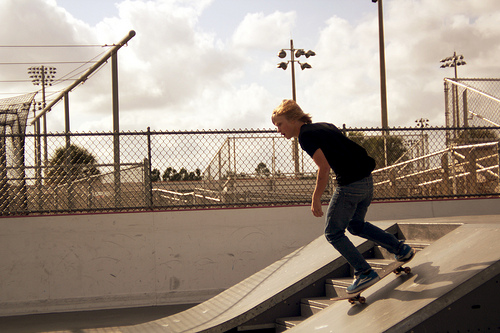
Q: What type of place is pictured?
A: It is a park.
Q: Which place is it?
A: It is a park.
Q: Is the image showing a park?
A: Yes, it is showing a park.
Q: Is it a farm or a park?
A: It is a park.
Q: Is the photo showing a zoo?
A: No, the picture is showing a park.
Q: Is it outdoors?
A: Yes, it is outdoors.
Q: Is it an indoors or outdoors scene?
A: It is outdoors.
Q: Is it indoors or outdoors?
A: It is outdoors.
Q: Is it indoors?
A: No, it is outdoors.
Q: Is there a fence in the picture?
A: Yes, there is a fence.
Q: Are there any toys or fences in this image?
A: Yes, there is a fence.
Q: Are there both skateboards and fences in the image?
A: Yes, there are both a fence and a skateboard.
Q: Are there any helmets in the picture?
A: No, there are no helmets.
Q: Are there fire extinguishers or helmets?
A: No, there are no helmets or fire extinguishers.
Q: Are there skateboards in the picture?
A: Yes, there is a skateboard.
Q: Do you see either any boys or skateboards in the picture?
A: Yes, there is a skateboard.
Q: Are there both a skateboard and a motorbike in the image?
A: No, there is a skateboard but no motorcycles.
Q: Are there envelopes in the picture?
A: No, there are no envelopes.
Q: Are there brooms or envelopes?
A: No, there are no envelopes or brooms.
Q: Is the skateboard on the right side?
A: Yes, the skateboard is on the right of the image.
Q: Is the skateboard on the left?
A: No, the skateboard is on the right of the image.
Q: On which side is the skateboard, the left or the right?
A: The skateboard is on the right of the image.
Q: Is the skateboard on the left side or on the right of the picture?
A: The skateboard is on the right of the image.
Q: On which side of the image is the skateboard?
A: The skateboard is on the right of the image.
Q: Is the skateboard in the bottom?
A: Yes, the skateboard is in the bottom of the image.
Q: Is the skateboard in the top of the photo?
A: No, the skateboard is in the bottom of the image.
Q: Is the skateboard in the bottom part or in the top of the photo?
A: The skateboard is in the bottom of the image.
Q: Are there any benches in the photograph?
A: No, there are no benches.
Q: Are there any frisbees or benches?
A: No, there are no benches or frisbees.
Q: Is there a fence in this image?
A: Yes, there is a fence.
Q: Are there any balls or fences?
A: Yes, there is a fence.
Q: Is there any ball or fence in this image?
A: Yes, there is a fence.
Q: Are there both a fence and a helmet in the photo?
A: No, there is a fence but no helmets.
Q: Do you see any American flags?
A: No, there are no American flags.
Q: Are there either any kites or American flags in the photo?
A: No, there are no American flags or kites.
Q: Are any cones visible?
A: No, there are no cones.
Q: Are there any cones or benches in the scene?
A: No, there are no cones or benches.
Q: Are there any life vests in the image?
A: No, there are no life vests.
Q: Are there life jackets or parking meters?
A: No, there are no life jackets or parking meters.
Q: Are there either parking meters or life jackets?
A: No, there are no life jackets or parking meters.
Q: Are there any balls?
A: No, there are no balls.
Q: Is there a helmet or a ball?
A: No, there are no balls or helmets.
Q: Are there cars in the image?
A: No, there are no cars.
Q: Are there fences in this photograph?
A: Yes, there is a fence.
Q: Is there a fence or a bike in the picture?
A: Yes, there is a fence.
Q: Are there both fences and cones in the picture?
A: No, there is a fence but no cones.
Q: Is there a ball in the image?
A: No, there are no balls.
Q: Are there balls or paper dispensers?
A: No, there are no balls or paper dispensers.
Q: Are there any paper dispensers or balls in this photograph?
A: No, there are no balls or paper dispensers.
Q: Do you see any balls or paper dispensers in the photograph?
A: No, there are no balls or paper dispensers.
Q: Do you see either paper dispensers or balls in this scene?
A: No, there are no balls or paper dispensers.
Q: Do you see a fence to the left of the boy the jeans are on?
A: Yes, there is a fence to the left of the boy.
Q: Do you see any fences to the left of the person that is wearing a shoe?
A: Yes, there is a fence to the left of the boy.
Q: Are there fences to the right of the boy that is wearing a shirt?
A: No, the fence is to the left of the boy.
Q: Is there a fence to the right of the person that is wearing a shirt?
A: No, the fence is to the left of the boy.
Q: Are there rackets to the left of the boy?
A: No, there is a fence to the left of the boy.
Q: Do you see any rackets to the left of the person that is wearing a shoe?
A: No, there is a fence to the left of the boy.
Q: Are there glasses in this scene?
A: No, there are no glasses.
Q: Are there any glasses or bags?
A: No, there are no glasses or bags.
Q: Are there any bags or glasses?
A: No, there are no glasses or bags.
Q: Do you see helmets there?
A: No, there are no helmets.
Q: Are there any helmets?
A: No, there are no helmets.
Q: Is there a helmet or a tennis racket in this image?
A: No, there are no helmets or rackets.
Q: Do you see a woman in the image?
A: No, there are no women.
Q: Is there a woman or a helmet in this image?
A: No, there are no women or helmets.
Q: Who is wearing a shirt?
A: The boy is wearing a shirt.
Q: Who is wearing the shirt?
A: The boy is wearing a shirt.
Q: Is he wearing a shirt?
A: Yes, the boy is wearing a shirt.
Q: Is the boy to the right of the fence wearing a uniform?
A: No, the boy is wearing a shirt.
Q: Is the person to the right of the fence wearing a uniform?
A: No, the boy is wearing a shirt.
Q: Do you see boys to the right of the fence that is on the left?
A: Yes, there is a boy to the right of the fence.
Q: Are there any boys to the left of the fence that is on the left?
A: No, the boy is to the right of the fence.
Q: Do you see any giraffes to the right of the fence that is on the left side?
A: No, there is a boy to the right of the fence.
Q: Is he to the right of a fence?
A: Yes, the boy is to the right of a fence.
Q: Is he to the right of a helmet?
A: No, the boy is to the right of a fence.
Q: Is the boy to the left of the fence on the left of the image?
A: No, the boy is to the right of the fence.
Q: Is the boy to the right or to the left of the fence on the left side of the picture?
A: The boy is to the right of the fence.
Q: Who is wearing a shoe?
A: The boy is wearing a shoe.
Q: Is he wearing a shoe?
A: Yes, the boy is wearing a shoe.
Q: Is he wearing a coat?
A: No, the boy is wearing a shoe.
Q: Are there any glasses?
A: No, there are no glasses.